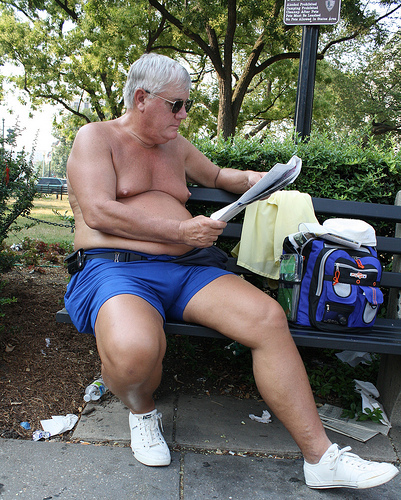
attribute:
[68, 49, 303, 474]
man — shirtless, overweight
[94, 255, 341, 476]
legs — clean, shaven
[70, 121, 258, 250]
arms — clean, shaven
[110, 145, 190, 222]
chest — shaven, clean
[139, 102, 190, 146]
face — clean, shaven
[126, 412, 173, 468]
shoes — white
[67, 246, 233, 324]
shorts — blue, worn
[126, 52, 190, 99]
hair — white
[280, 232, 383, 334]
bag — carry-on, blue, small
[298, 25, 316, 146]
poll — metal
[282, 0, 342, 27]
sign — brown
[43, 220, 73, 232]
chain — hanging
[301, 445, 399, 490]
sneaker — white, very white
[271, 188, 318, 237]
shirt — yellow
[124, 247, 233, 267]
fanny pack — black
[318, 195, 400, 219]
wood — blue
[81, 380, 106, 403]
water bottle — discarded, plastic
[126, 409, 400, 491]
sneakers — white